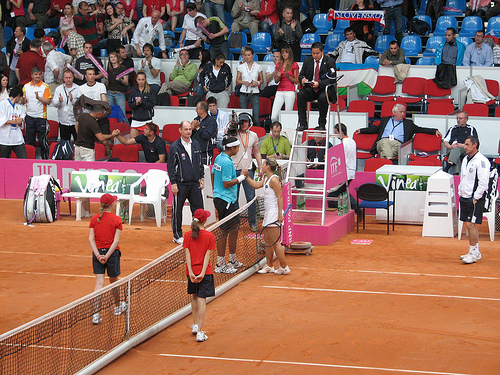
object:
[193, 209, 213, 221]
hat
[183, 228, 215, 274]
shirt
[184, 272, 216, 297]
shorts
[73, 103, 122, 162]
men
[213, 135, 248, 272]
women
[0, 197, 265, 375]
net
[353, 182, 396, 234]
chair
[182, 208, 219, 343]
woman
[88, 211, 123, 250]
shirt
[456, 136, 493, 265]
man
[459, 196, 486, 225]
shorts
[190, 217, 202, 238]
hair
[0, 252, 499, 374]
court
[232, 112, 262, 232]
man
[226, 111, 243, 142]
camera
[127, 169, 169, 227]
chair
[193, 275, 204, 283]
hands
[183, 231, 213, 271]
back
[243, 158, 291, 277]
woman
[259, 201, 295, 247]
racket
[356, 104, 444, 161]
man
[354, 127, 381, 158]
chair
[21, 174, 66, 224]
bag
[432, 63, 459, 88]
clothing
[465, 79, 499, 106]
chair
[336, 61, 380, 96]
banner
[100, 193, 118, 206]
cap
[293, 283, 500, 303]
line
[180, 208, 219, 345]
girls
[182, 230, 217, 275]
shirts